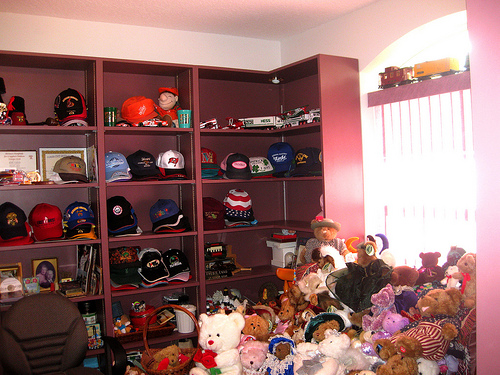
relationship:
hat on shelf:
[63, 201, 94, 228] [4, 49, 359, 373]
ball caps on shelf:
[101, 82, 203, 337] [4, 49, 359, 373]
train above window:
[384, 44, 485, 111] [346, 124, 498, 245]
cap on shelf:
[198, 141, 223, 190] [203, 170, 322, 184]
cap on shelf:
[213, 144, 251, 179] [203, 170, 322, 184]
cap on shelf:
[244, 148, 274, 181] [203, 170, 322, 184]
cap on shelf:
[290, 138, 323, 178] [203, 170, 322, 184]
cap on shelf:
[268, 138, 296, 175] [203, 170, 322, 184]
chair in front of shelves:
[0, 292, 129, 373] [0, 51, 364, 371]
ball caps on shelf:
[105, 163, 202, 327] [109, 271, 199, 296]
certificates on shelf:
[2, 143, 89, 189] [0, 179, 98, 192]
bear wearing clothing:
[407, 285, 464, 360] [411, 315, 454, 357]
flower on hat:
[313, 211, 327, 222] [307, 214, 341, 229]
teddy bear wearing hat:
[300, 213, 349, 265] [307, 214, 341, 229]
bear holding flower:
[188, 311, 248, 374] [190, 348, 200, 363]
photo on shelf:
[32, 255, 59, 291] [7, 278, 102, 301]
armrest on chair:
[92, 335, 128, 373] [11, 274, 118, 366]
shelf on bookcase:
[106, 121, 194, 133] [97, 57, 204, 368]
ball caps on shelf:
[101, 82, 203, 337] [106, 121, 194, 133]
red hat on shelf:
[27, 201, 64, 242] [0, 235, 101, 251]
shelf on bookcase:
[0, 235, 101, 251] [0, 49, 112, 373]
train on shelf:
[377, 51, 469, 85] [368, 77, 474, 104]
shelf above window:
[368, 77, 474, 104] [359, 11, 476, 265]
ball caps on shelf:
[101, 82, 203, 337] [106, 175, 195, 185]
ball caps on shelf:
[101, 82, 203, 337] [104, 230, 197, 242]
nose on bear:
[206, 338, 216, 345] [185, 304, 247, 374]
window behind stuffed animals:
[359, 11, 476, 265] [154, 218, 474, 373]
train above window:
[377, 51, 469, 85] [369, 87, 481, 267]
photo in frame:
[32, 255, 59, 291] [32, 256, 59, 290]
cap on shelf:
[0, 200, 28, 241] [1, 220, 311, 253]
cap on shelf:
[30, 200, 62, 244] [1, 220, 311, 253]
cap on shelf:
[63, 202, 99, 240] [1, 220, 311, 253]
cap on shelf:
[62, 220, 99, 240] [1, 220, 311, 253]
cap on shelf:
[6, 227, 33, 247] [1, 220, 311, 253]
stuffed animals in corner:
[154, 218, 480, 374] [263, 34, 425, 355]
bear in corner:
[188, 311, 248, 374] [263, 34, 425, 355]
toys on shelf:
[202, 106, 324, 128] [4, 49, 359, 373]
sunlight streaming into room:
[312, 154, 480, 219] [9, 35, 498, 363]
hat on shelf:
[28, 203, 63, 238] [5, 233, 105, 257]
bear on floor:
[407, 285, 464, 360] [126, 358, 463, 369]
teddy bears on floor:
[348, 284, 410, 344] [126, 358, 463, 369]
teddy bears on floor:
[282, 293, 330, 346] [126, 358, 463, 369]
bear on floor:
[188, 311, 248, 374] [126, 358, 463, 369]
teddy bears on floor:
[239, 315, 269, 360] [126, 358, 463, 369]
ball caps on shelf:
[101, 82, 203, 337] [207, 173, 323, 187]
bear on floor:
[190, 317, 244, 370] [168, 364, 472, 373]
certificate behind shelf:
[37, 144, 91, 185] [4, 180, 103, 190]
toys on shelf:
[202, 106, 340, 128] [197, 117, 327, 138]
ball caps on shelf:
[101, 82, 203, 337] [109, 229, 196, 242]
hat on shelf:
[265, 140, 297, 173] [203, 219, 279, 234]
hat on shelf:
[222, 185, 253, 219] [189, 220, 269, 244]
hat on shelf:
[223, 152, 253, 179] [104, 153, 322, 196]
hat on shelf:
[203, 191, 225, 233] [104, 153, 322, 196]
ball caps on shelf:
[101, 82, 203, 337] [104, 153, 322, 196]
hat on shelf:
[269, 141, 293, 171] [104, 153, 322, 196]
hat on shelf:
[28, 203, 63, 238] [104, 153, 322, 196]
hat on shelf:
[247, 154, 276, 178] [209, 175, 323, 188]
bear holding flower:
[188, 311, 248, 374] [201, 349, 218, 357]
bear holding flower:
[188, 311, 248, 374] [197, 354, 215, 368]